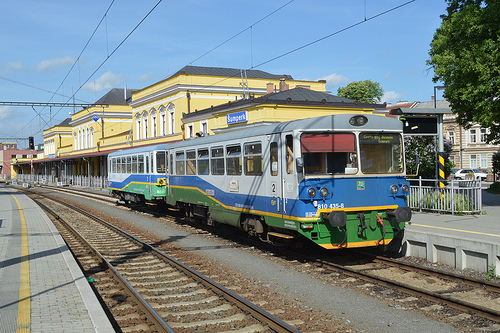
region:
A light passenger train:
[282, 125, 400, 227]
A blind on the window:
[308, 135, 352, 150]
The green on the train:
[179, 190, 198, 197]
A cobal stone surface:
[45, 287, 70, 329]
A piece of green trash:
[85, 275, 92, 280]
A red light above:
[29, 141, 34, 145]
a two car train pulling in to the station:
[103, 119, 411, 254]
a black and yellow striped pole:
[438, 155, 447, 197]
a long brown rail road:
[17, 184, 300, 330]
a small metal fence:
[411, 175, 481, 212]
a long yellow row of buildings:
[12, 75, 387, 187]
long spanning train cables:
[13, 0, 415, 145]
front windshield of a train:
[299, 133, 405, 171]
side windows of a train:
[243, 143, 267, 173]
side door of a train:
[266, 130, 295, 227]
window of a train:
[294, 130, 351, 172]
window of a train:
[358, 130, 409, 173]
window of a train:
[280, 137, 300, 173]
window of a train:
[262, 136, 282, 173]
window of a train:
[245, 142, 268, 172]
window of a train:
[225, 137, 246, 179]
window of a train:
[209, 142, 225, 176]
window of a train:
[192, 145, 206, 177]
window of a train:
[170, 147, 188, 176]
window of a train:
[151, 144, 171, 175]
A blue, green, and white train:
[112, 113, 412, 245]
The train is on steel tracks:
[341, 244, 484, 314]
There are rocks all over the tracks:
[73, 215, 211, 328]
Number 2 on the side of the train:
[266, 168, 281, 206]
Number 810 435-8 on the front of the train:
[303, 197, 360, 213]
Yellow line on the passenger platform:
[11, 188, 52, 332]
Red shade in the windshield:
[293, 124, 364, 156]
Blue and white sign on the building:
[217, 109, 262, 123]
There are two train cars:
[84, 113, 417, 264]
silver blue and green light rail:
[107, 129, 370, 244]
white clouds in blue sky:
[18, 15, 56, 42]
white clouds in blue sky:
[22, 45, 73, 77]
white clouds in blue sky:
[214, 3, 246, 32]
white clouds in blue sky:
[37, 19, 77, 47]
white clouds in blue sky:
[9, 30, 54, 66]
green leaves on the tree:
[462, 26, 492, 65]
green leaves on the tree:
[427, 49, 479, 138]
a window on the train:
[250, 141, 260, 164]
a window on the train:
[307, 135, 342, 165]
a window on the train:
[220, 153, 227, 167]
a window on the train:
[205, 144, 232, 176]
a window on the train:
[185, 149, 210, 171]